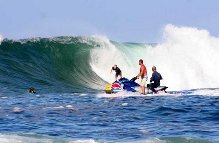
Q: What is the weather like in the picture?
A: It is clear.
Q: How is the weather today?
A: It is clear.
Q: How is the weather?
A: It is clear.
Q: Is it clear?
A: Yes, it is clear.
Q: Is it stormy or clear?
A: It is clear.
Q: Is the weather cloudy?
A: No, it is clear.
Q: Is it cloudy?
A: No, it is clear.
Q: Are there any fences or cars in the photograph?
A: No, there are no fences or cars.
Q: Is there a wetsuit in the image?
A: Yes, there is a wetsuit.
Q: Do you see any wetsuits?
A: Yes, there is a wetsuit.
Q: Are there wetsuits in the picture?
A: Yes, there is a wetsuit.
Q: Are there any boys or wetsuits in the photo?
A: Yes, there is a wetsuit.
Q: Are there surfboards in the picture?
A: No, there are no surfboards.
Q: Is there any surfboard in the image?
A: No, there are no surfboards.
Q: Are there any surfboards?
A: No, there are no surfboards.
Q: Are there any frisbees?
A: No, there are no frisbees.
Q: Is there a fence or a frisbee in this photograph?
A: No, there are no frisbees or fences.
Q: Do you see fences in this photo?
A: No, there are no fences.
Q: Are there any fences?
A: No, there are no fences.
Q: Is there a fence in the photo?
A: No, there are no fences.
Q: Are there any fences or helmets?
A: No, there are no fences or helmets.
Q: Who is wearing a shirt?
A: The man is wearing a shirt.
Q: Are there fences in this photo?
A: No, there are no fences.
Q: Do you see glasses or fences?
A: No, there are no fences or glasses.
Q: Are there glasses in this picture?
A: No, there are no glasses.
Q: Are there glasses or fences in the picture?
A: No, there are no glasses or fences.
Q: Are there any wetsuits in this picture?
A: Yes, there is a wetsuit.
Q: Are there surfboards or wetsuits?
A: Yes, there is a wetsuit.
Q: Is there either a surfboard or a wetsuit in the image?
A: Yes, there is a wetsuit.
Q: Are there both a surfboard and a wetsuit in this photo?
A: No, there is a wetsuit but no surfboards.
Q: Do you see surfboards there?
A: No, there are no surfboards.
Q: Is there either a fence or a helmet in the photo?
A: No, there are no fences or helmets.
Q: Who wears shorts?
A: The man wears shorts.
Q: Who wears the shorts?
A: The man wears shorts.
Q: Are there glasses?
A: No, there are no glasses.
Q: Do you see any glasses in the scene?
A: No, there are no glasses.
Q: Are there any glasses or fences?
A: No, there are no glasses or fences.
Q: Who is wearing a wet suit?
A: The man is wearing a wet suit.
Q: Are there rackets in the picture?
A: No, there are no rackets.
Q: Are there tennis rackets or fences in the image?
A: No, there are no tennis rackets or fences.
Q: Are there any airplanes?
A: No, there are no airplanes.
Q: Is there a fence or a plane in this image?
A: No, there are no airplanes or fences.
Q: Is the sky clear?
A: Yes, the sky is clear.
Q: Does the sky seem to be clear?
A: Yes, the sky is clear.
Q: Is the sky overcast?
A: No, the sky is clear.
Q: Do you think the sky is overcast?
A: No, the sky is clear.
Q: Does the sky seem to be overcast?
A: No, the sky is clear.